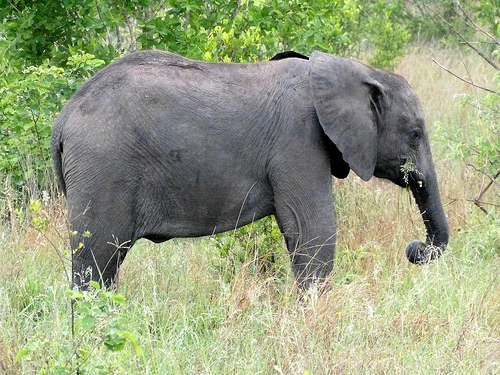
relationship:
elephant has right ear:
[49, 44, 452, 302] [305, 45, 383, 181]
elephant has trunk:
[49, 44, 452, 302] [404, 169, 450, 275]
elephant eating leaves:
[49, 44, 452, 302] [396, 153, 425, 193]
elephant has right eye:
[49, 44, 452, 302] [409, 123, 424, 142]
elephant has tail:
[49, 44, 452, 302] [46, 115, 69, 206]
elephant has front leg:
[49, 44, 452, 302] [263, 132, 341, 292]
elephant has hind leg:
[49, 44, 452, 302] [65, 163, 138, 292]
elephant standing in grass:
[49, 44, 452, 302] [2, 44, 499, 371]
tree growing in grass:
[26, 203, 129, 372] [2, 44, 499, 371]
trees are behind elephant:
[2, 2, 421, 210] [49, 44, 452, 302]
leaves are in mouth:
[396, 153, 425, 193] [397, 156, 417, 197]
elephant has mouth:
[49, 44, 452, 302] [397, 156, 417, 197]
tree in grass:
[26, 203, 129, 372] [2, 44, 499, 371]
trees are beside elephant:
[2, 2, 421, 210] [49, 44, 452, 302]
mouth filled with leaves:
[397, 156, 417, 197] [396, 153, 425, 193]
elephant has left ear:
[49, 44, 452, 302] [268, 51, 349, 183]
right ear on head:
[305, 45, 383, 181] [311, 43, 449, 267]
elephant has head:
[49, 44, 452, 302] [311, 43, 449, 267]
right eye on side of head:
[409, 123, 424, 142] [311, 43, 449, 267]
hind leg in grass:
[65, 163, 138, 292] [2, 44, 499, 371]